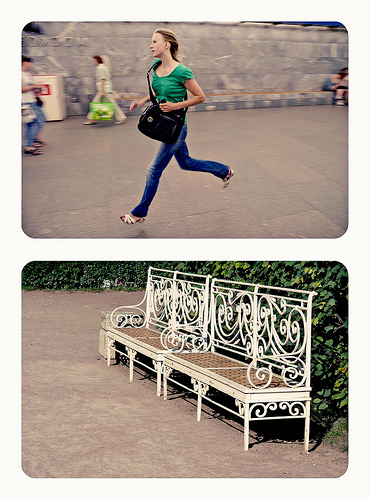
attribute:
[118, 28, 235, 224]
woman — running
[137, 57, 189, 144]
purse — black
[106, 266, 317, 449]
benches — white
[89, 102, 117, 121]
bag — green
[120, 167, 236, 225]
sandals — white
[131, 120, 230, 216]
jeans — blue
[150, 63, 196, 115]
shirt — green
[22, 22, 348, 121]
wall — permanent, brick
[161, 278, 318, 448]
bench — metallic, white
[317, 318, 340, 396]
leaves — green, several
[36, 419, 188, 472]
ground — sandy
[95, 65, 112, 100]
shirt — yellow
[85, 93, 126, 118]
pants — tan